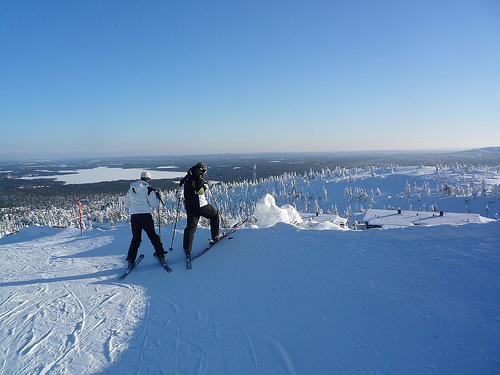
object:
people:
[126, 172, 168, 258]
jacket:
[125, 178, 165, 216]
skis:
[123, 253, 150, 278]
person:
[178, 163, 222, 255]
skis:
[180, 244, 199, 269]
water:
[91, 168, 141, 182]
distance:
[8, 141, 214, 158]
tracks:
[16, 291, 94, 363]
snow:
[104, 291, 499, 374]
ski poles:
[168, 198, 177, 252]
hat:
[138, 169, 151, 180]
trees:
[60, 215, 70, 229]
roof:
[362, 206, 482, 224]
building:
[362, 202, 486, 230]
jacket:
[178, 174, 215, 206]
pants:
[126, 214, 166, 256]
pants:
[182, 206, 221, 255]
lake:
[11, 165, 196, 186]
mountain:
[18, 151, 493, 372]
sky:
[5, 3, 493, 81]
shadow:
[94, 285, 241, 372]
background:
[17, 153, 492, 168]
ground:
[10, 222, 498, 365]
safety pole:
[76, 205, 84, 231]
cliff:
[41, 215, 498, 244]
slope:
[350, 203, 499, 369]